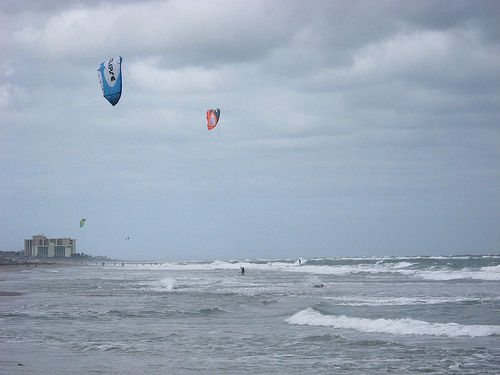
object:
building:
[16, 234, 86, 261]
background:
[1, 215, 139, 267]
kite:
[92, 47, 127, 109]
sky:
[1, 1, 498, 248]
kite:
[201, 106, 223, 132]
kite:
[77, 217, 87, 228]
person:
[238, 266, 247, 278]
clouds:
[2, 1, 499, 184]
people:
[101, 262, 106, 267]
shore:
[0, 249, 169, 267]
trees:
[81, 252, 85, 258]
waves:
[286, 307, 500, 334]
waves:
[130, 257, 500, 283]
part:
[8, 269, 390, 375]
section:
[23, 233, 78, 260]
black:
[296, 258, 302, 264]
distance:
[17, 232, 83, 268]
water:
[1, 265, 498, 374]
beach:
[1, 256, 162, 271]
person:
[121, 261, 125, 266]